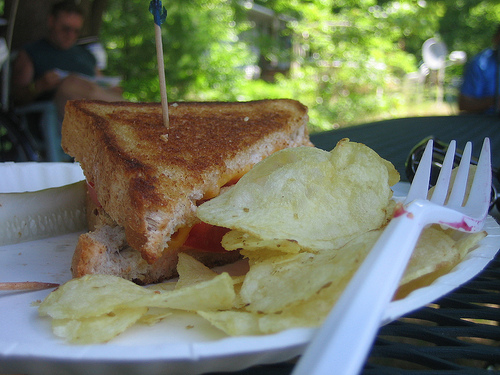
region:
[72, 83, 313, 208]
sandwich on a plate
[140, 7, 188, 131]
toothpick in the sandwich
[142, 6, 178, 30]
blue frill on the toothpick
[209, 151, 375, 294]
potato chips on the plate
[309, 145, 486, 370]
plastic fork on the plate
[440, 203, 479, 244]
food on the fork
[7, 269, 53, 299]
toothpick on the plate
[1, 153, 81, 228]
dish on the table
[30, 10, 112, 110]
man in the background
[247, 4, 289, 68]
house in the background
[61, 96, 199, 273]
a toasted cheese sandwich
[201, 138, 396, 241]
a plate of potato chips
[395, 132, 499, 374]
a plastic fork on the paper plate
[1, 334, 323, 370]
a paper plate on the table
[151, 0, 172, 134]
a toothpick skewer to hold the sandwich together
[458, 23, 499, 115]
a man in a blue shirt sitting at the table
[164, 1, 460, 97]
green foliage in the background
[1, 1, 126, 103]
a man reading in the background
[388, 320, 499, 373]
an iron weaved design table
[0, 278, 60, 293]
the tip of a toothpick skewer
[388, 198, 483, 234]
Red food on the plastic fork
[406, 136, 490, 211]
The prongs on the plastic fork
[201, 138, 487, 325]
the potato chips on the white palte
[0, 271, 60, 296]
a toothpick on the white plate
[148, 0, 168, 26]
Blue wrapper on the tooothpick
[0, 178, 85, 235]
A pickle on the white plate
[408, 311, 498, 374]
Holes in the picnic table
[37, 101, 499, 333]
A sandwich and chips on the plate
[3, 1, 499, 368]
Lunch on the picnic table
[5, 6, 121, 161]
A man in a green shirt sitting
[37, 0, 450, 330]
A lunch platter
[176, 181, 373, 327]
Some potato chips on a paper plate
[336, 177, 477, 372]
A white plastic fork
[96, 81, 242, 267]
A sandwich on a paper plate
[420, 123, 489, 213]
A pair of sunglasses on the table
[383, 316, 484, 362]
A metal grate table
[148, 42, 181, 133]
A toothpick sticking out of the sandwich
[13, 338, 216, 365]
A paper plate with lunch on it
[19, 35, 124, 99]
A man reading in the background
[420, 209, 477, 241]
Red sauce on the fork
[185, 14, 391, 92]
these are some trees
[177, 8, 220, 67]
the leaves are green in color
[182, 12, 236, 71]
the leaves are big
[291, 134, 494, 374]
this is a fork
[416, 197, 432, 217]
the fork is made of plastic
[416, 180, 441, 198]
the fork is white in color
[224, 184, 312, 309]
these are some crisps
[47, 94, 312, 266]
this is a sandwich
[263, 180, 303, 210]
the crisps are yellow in color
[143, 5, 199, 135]
this is a toothpick